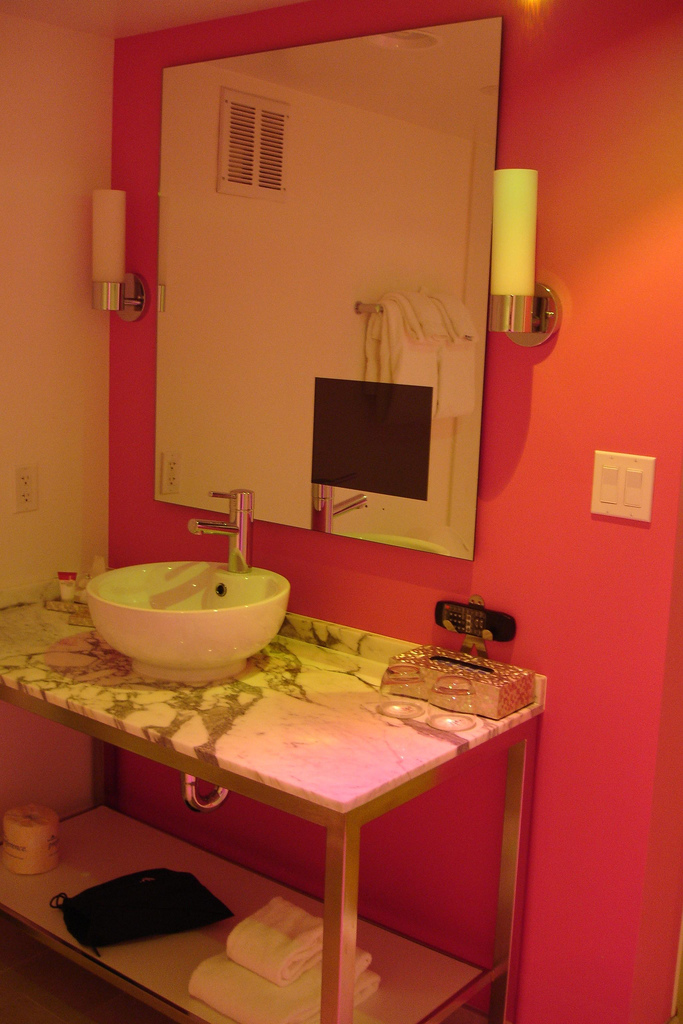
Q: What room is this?
A: It is a bathroom.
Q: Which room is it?
A: It is a bathroom.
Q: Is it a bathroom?
A: Yes, it is a bathroom.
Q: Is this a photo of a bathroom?
A: Yes, it is showing a bathroom.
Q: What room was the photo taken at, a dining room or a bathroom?
A: It was taken at a bathroom.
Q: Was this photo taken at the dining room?
A: No, the picture was taken in the bathroom.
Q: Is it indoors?
A: Yes, it is indoors.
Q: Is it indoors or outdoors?
A: It is indoors.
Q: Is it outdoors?
A: No, it is indoors.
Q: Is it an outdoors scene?
A: No, it is indoors.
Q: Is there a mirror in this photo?
A: Yes, there is a mirror.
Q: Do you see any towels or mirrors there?
A: Yes, there is a mirror.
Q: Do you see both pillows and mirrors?
A: No, there is a mirror but no pillows.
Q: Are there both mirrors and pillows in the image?
A: No, there is a mirror but no pillows.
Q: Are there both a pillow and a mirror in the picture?
A: No, there is a mirror but no pillows.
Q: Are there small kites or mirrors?
A: Yes, there is a small mirror.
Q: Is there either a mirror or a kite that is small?
A: Yes, the mirror is small.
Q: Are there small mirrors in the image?
A: Yes, there is a small mirror.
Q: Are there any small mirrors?
A: Yes, there is a small mirror.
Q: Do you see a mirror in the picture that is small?
A: Yes, there is a mirror that is small.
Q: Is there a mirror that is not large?
A: Yes, there is a small mirror.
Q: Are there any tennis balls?
A: No, there are no tennis balls.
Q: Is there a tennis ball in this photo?
A: No, there are no tennis balls.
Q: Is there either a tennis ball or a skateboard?
A: No, there are no tennis balls or skateboards.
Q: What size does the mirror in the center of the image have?
A: The mirror has small size.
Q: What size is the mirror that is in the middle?
A: The mirror is small.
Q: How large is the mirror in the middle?
A: The mirror is small.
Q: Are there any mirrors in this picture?
A: Yes, there is a mirror.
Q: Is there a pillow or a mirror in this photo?
A: Yes, there is a mirror.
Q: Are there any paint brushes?
A: No, there are no paint brushes.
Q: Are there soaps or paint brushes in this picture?
A: No, there are no paint brushes or soaps.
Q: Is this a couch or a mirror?
A: This is a mirror.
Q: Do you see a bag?
A: Yes, there is a bag.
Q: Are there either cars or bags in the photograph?
A: Yes, there is a bag.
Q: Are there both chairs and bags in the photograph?
A: No, there is a bag but no chairs.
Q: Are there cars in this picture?
A: No, there are no cars.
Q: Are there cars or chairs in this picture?
A: No, there are no cars or chairs.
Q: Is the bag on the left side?
A: Yes, the bag is on the left of the image.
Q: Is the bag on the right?
A: No, the bag is on the left of the image.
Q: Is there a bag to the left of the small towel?
A: Yes, there is a bag to the left of the towel.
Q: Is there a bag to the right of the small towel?
A: No, the bag is to the left of the towel.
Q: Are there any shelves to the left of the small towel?
A: No, there is a bag to the left of the towel.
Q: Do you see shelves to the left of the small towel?
A: No, there is a bag to the left of the towel.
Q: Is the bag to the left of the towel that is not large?
A: Yes, the bag is to the left of the towel.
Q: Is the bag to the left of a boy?
A: No, the bag is to the left of the towel.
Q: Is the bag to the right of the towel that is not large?
A: No, the bag is to the left of the towel.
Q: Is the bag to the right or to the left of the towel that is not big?
A: The bag is to the left of the towel.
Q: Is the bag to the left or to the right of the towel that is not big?
A: The bag is to the left of the towel.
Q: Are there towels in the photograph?
A: Yes, there is a towel.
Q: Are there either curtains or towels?
A: Yes, there is a towel.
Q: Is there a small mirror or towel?
A: Yes, there is a small towel.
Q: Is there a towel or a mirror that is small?
A: Yes, the towel is small.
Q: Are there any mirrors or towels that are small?
A: Yes, the towel is small.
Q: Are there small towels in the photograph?
A: Yes, there is a small towel.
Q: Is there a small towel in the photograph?
A: Yes, there is a small towel.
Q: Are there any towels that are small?
A: Yes, there is a small towel.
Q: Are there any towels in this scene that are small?
A: Yes, there is a towel that is small.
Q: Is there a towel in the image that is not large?
A: Yes, there is a small towel.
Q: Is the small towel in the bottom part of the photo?
A: Yes, the towel is in the bottom of the image.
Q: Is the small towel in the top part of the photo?
A: No, the towel is in the bottom of the image.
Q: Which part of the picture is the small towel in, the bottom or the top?
A: The towel is in the bottom of the image.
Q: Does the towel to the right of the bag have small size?
A: Yes, the towel is small.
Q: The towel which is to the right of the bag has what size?
A: The towel is small.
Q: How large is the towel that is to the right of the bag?
A: The towel is small.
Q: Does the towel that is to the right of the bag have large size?
A: No, the towel is small.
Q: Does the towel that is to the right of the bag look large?
A: No, the towel is small.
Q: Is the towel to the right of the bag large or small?
A: The towel is small.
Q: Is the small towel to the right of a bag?
A: Yes, the towel is to the right of a bag.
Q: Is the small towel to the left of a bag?
A: No, the towel is to the right of a bag.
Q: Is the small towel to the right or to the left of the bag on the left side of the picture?
A: The towel is to the right of the bag.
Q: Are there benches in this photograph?
A: No, there are no benches.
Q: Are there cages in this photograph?
A: No, there are no cages.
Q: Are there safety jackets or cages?
A: No, there are no cages or safety jackets.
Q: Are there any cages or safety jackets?
A: No, there are no cages or safety jackets.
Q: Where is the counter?
A: The counter is in the bathroom.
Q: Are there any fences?
A: No, there are no fences.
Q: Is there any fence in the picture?
A: No, there are no fences.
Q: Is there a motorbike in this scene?
A: No, there are no motorcycles.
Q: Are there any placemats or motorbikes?
A: No, there are no motorbikes or placemats.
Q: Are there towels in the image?
A: Yes, there is a towel.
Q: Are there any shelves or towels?
A: Yes, there is a towel.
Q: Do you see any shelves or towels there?
A: Yes, there is a towel.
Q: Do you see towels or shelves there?
A: Yes, there is a towel.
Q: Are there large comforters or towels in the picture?
A: Yes, there is a large towel.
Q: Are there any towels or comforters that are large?
A: Yes, the towel is large.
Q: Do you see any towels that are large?
A: Yes, there is a large towel.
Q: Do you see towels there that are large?
A: Yes, there is a towel that is large.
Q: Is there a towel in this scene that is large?
A: Yes, there is a towel that is large.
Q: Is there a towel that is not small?
A: Yes, there is a large towel.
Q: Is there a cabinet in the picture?
A: No, there are no cabinets.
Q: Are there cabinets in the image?
A: No, there are no cabinets.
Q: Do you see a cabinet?
A: No, there are no cabinets.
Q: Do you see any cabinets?
A: No, there are no cabinets.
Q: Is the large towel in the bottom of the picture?
A: Yes, the towel is in the bottom of the image.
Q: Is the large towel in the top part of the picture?
A: No, the towel is in the bottom of the image.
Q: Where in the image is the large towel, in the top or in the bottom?
A: The towel is in the bottom of the image.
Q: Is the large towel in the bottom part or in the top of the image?
A: The towel is in the bottom of the image.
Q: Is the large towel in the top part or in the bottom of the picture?
A: The towel is in the bottom of the image.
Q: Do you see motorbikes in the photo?
A: No, there are no motorbikes.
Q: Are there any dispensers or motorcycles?
A: No, there are no motorcycles or dispensers.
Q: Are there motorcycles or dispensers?
A: No, there are no motorcycles or dispensers.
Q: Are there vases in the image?
A: No, there are no vases.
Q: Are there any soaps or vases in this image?
A: No, there are no vases or soaps.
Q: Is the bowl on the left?
A: Yes, the bowl is on the left of the image.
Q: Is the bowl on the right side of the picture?
A: No, the bowl is on the left of the image.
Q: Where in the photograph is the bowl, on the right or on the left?
A: The bowl is on the left of the image.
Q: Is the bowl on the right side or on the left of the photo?
A: The bowl is on the left of the image.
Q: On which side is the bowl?
A: The bowl is on the left of the image.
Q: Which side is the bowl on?
A: The bowl is on the left of the image.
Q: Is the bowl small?
A: Yes, the bowl is small.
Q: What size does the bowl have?
A: The bowl has small size.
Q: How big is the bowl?
A: The bowl is small.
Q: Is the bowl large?
A: No, the bowl is small.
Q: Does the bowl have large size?
A: No, the bowl is small.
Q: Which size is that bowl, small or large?
A: The bowl is small.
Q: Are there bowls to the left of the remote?
A: Yes, there is a bowl to the left of the remote.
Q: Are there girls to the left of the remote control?
A: No, there is a bowl to the left of the remote control.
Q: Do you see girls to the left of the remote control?
A: No, there is a bowl to the left of the remote control.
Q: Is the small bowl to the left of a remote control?
A: Yes, the bowl is to the left of a remote control.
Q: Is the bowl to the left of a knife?
A: No, the bowl is to the left of a remote control.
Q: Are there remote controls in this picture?
A: Yes, there is a remote control.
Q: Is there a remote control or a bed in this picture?
A: Yes, there is a remote control.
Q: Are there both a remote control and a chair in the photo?
A: No, there is a remote control but no chairs.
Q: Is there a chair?
A: No, there are no chairs.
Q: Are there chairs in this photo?
A: No, there are no chairs.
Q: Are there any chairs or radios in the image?
A: No, there are no chairs or radios.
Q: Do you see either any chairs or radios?
A: No, there are no chairs or radios.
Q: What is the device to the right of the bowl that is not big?
A: The device is a remote control.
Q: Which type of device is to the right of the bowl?
A: The device is a remote control.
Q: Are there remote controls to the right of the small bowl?
A: Yes, there is a remote control to the right of the bowl.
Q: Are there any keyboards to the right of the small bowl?
A: No, there is a remote control to the right of the bowl.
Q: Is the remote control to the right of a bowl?
A: Yes, the remote control is to the right of a bowl.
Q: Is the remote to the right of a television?
A: No, the remote is to the right of a bowl.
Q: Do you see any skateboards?
A: No, there are no skateboards.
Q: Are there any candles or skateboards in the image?
A: No, there are no skateboards or candles.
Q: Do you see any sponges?
A: No, there are no sponges.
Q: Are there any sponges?
A: No, there are no sponges.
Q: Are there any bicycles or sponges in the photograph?
A: No, there are no sponges or bicycles.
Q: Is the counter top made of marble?
A: Yes, the counter top is made of marble.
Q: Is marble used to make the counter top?
A: Yes, the counter top is made of marble.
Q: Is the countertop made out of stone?
A: No, the countertop is made of marble.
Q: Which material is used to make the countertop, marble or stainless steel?
A: The countertop is made of marble.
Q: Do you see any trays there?
A: No, there are no trays.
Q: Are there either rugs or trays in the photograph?
A: No, there are no trays or rugs.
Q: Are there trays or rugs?
A: No, there are no trays or rugs.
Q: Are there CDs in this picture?
A: No, there are no cds.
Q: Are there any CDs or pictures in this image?
A: No, there are no CDs or pictures.